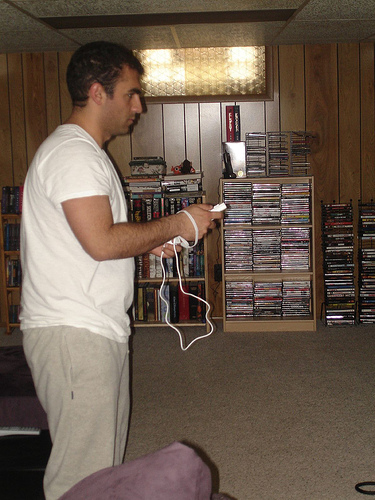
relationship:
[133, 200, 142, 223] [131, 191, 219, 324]
book on bookshelf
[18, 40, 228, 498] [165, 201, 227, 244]
man holding controller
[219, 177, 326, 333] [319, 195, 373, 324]
case of dvds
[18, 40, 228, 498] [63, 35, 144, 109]
man with hair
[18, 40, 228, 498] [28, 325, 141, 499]
man wearing pants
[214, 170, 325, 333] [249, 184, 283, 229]
case with dvds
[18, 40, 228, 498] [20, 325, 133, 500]
man wearing pants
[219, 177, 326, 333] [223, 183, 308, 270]
case of cds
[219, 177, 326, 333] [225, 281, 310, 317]
case of cds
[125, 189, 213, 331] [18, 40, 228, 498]
bookshelf behind man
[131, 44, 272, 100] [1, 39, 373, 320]
light on top of wall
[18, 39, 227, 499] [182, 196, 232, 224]
man holds white controller